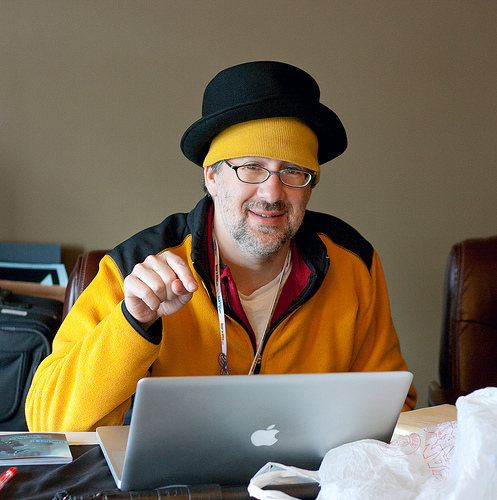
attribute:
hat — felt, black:
[178, 61, 349, 166]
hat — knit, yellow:
[202, 117, 321, 186]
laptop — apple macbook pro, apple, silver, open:
[94, 370, 415, 491]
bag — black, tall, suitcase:
[1, 288, 62, 432]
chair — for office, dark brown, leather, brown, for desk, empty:
[428, 235, 496, 406]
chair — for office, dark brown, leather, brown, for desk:
[61, 248, 112, 323]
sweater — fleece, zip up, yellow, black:
[25, 194, 417, 432]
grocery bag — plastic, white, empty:
[247, 387, 497, 499]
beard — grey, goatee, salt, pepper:
[218, 183, 309, 261]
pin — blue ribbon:
[216, 351, 230, 375]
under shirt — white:
[238, 251, 291, 350]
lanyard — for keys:
[211, 228, 293, 375]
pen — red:
[1, 467, 20, 490]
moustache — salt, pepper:
[244, 200, 291, 212]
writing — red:
[379, 419, 458, 482]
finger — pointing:
[164, 251, 200, 293]